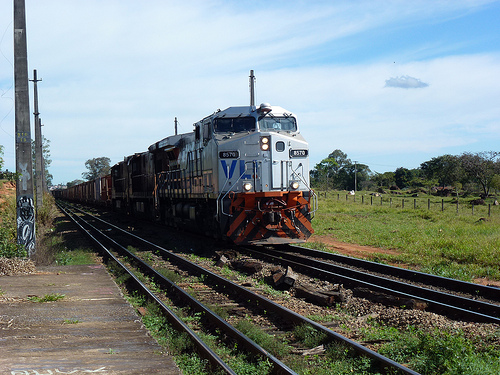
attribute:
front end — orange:
[210, 68, 312, 240]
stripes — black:
[221, 189, 312, 241]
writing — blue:
[218, 156, 255, 181]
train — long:
[44, 87, 311, 247]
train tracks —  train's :
[322, 247, 470, 299]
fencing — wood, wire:
[316, 182, 496, 235]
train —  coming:
[48, 103, 403, 286]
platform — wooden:
[2, 268, 173, 374]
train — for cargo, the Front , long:
[53, 68, 329, 241]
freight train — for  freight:
[52, 67, 315, 247]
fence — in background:
[327, 177, 492, 227]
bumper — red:
[212, 184, 338, 247]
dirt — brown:
[278, 216, 449, 341]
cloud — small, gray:
[380, 71, 430, 90]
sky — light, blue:
[204, 90, 273, 150]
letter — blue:
[220, 158, 238, 183]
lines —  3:
[133, 254, 344, 372]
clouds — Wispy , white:
[288, 72, 465, 131]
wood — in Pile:
[213, 247, 350, 305]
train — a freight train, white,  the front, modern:
[53, 105, 314, 243]